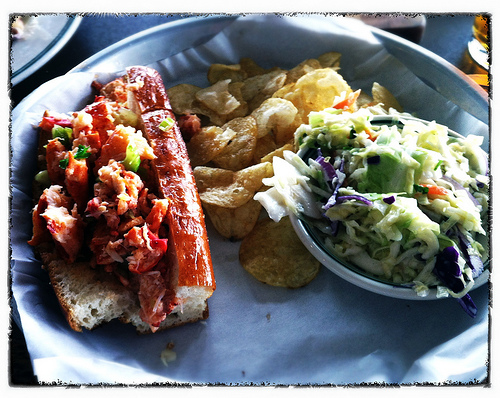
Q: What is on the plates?
A: Food.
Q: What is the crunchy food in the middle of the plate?
A: Chips.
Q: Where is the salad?
A: In a bowl.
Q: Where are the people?
A: There are no people in the photo.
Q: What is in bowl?
A: Coleslaw.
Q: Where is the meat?
A: In bun.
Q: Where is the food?
A: On plate.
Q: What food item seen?
A: Sandwich.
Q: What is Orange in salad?
A: Carrot.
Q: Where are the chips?
A: On table.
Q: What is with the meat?
A: Bread.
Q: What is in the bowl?
A: Salad.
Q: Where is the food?
A: On plate.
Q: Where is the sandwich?
A: Plate.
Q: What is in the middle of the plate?
A: Deep fried food.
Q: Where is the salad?
A: Small blue bowl.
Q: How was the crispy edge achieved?
A: Toasted roll.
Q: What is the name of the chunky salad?
A: Coleslaw.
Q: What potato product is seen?
A: Potato chips.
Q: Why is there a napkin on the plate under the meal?
A: Absorb grease.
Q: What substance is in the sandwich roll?
A: Meat mixture.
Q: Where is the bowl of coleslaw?
A: On the right side of the plate.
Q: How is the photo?
A: Clear.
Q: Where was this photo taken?
A: In a restaurant.